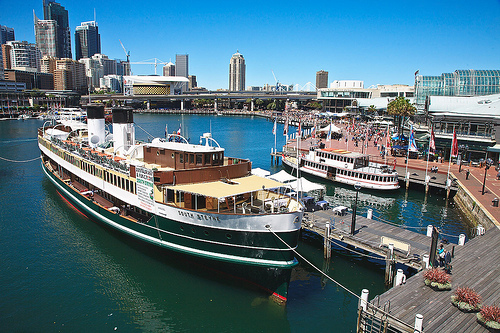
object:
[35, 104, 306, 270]
boat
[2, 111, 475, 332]
water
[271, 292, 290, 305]
stripe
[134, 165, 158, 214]
poster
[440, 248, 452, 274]
people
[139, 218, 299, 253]
stripe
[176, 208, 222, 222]
name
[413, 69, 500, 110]
building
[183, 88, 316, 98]
train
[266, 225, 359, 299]
cable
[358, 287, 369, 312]
post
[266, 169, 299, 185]
tarp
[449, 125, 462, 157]
flag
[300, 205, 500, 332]
dock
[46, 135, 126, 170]
decoration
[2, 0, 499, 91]
sky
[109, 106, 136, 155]
pillar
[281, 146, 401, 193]
boat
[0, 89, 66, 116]
building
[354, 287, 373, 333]
pier